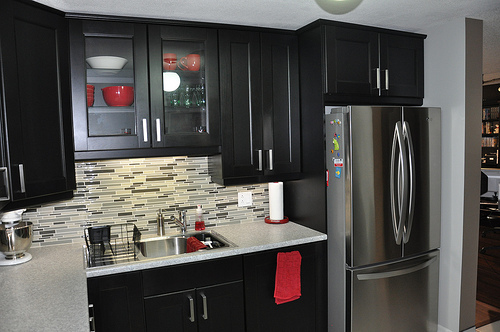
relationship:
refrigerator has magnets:
[348, 105, 441, 331] [333, 118, 342, 189]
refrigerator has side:
[348, 105, 441, 331] [330, 108, 346, 330]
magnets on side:
[333, 118, 342, 189] [330, 108, 346, 330]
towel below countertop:
[274, 249, 301, 300] [241, 228, 292, 238]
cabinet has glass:
[154, 34, 212, 147] [170, 50, 199, 127]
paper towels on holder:
[267, 182, 284, 217] [267, 215, 288, 226]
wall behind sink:
[99, 159, 203, 204] [138, 230, 229, 254]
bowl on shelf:
[88, 51, 125, 72] [88, 73, 135, 83]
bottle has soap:
[193, 205, 206, 232] [196, 223, 204, 232]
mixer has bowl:
[4, 210, 28, 266] [2, 228, 27, 250]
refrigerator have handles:
[348, 105, 441, 331] [387, 122, 416, 247]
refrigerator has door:
[348, 105, 441, 331] [349, 108, 402, 262]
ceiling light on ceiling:
[319, 3, 360, 12] [385, 4, 457, 19]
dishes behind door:
[88, 54, 134, 107] [77, 27, 146, 148]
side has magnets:
[330, 108, 346, 330] [333, 118, 342, 189]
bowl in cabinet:
[106, 86, 132, 108] [77, 27, 146, 148]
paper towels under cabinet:
[267, 182, 284, 217] [154, 34, 212, 147]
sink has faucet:
[138, 230, 229, 254] [176, 208, 187, 232]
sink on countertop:
[138, 230, 229, 254] [241, 228, 292, 238]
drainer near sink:
[85, 227, 140, 262] [138, 230, 229, 254]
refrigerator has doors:
[348, 105, 441, 331] [365, 121, 436, 154]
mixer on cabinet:
[4, 210, 28, 266] [17, 269, 50, 285]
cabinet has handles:
[154, 34, 212, 147] [139, 116, 166, 147]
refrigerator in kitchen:
[348, 105, 441, 331] [4, 11, 465, 326]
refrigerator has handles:
[348, 105, 441, 331] [387, 122, 416, 247]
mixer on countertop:
[4, 210, 28, 266] [241, 228, 292, 238]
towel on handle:
[274, 249, 301, 300] [279, 255, 299, 256]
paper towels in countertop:
[267, 182, 284, 217] [241, 228, 292, 238]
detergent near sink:
[193, 205, 206, 232] [138, 230, 229, 254]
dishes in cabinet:
[88, 54, 134, 107] [154, 34, 212, 147]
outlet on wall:
[236, 193, 251, 204] [99, 159, 203, 204]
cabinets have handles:
[12, 36, 298, 137] [139, 116, 166, 147]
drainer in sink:
[85, 227, 140, 262] [138, 230, 229, 254]